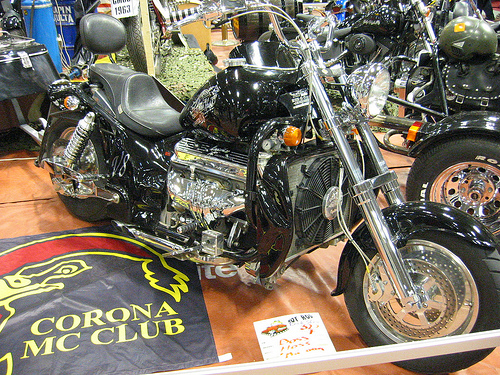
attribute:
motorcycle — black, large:
[34, 2, 499, 374]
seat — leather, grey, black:
[79, 10, 187, 140]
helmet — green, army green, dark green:
[438, 12, 497, 62]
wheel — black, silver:
[344, 230, 500, 374]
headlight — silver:
[345, 62, 391, 121]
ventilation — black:
[295, 153, 351, 247]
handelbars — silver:
[156, 0, 343, 53]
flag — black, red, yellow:
[0, 221, 220, 372]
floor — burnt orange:
[2, 26, 498, 374]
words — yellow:
[21, 300, 185, 360]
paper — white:
[251, 310, 338, 363]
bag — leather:
[1, 43, 59, 100]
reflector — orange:
[282, 123, 301, 148]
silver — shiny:
[165, 135, 248, 224]